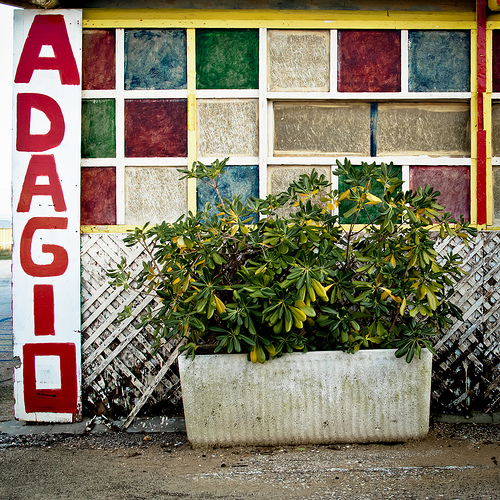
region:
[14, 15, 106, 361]
letters on the sign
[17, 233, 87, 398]
red letters on white background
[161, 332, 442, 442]
pot with plants in it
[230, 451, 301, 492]
ground in front of plants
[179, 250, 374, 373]
green leaves in the pot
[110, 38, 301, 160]
colorful wall above plants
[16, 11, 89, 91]
the letter A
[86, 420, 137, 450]
rocks on the ground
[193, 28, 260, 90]
green above the plant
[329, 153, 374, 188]
top part of the plant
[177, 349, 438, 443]
White dirty planter holding green plant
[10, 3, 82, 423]
Sign next to plant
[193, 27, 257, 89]
Green tile above white tile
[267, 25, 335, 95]
White dirty tile next to red tile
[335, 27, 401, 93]
Red tile next to blue tile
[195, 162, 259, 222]
Blue tile below white dirty tile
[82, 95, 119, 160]
Green tile next to red tile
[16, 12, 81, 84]
Letter A is red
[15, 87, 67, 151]
Letter D is red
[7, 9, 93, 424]
Sign leaning against wall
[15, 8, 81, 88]
Red Letter A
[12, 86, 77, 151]
Red Letter D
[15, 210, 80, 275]
Red letter G on white background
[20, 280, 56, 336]
Red Letter I on white background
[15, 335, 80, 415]
Red letter O on white background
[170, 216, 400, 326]
Green plant leaves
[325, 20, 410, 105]
Red and white box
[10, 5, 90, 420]
White ADAGIO sign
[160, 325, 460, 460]
White dirty planter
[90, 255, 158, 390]
White trellis on wall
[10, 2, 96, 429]
White sign has red lettering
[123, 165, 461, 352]
Plants are green and yellow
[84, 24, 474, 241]
Windows are colorful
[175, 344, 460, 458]
White planter box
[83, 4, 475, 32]
Yellow trim around windows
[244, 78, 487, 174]
One window is different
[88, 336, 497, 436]
Lattes looks moldy on the bottom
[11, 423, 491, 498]
Ground is dirt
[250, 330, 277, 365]
Plants have thick yellowing leaves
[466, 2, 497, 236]
Red trim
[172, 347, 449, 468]
white container on ground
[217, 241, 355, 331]
leaves of green plant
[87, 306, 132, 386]
white boards in criss cross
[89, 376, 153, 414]
dirt on white boards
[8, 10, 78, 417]
red letters vertical on sign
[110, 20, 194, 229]
colored squares on building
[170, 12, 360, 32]
yellow wood on building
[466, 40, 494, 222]
red and yellow wood on building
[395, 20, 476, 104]
blue box on building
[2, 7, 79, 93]
top letter on sign